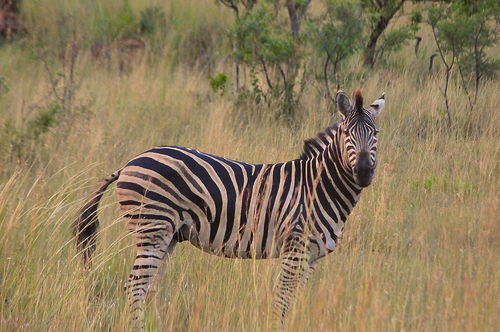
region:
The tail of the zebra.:
[64, 165, 121, 247]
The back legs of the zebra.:
[119, 207, 175, 322]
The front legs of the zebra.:
[274, 245, 311, 330]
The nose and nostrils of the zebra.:
[344, 155, 374, 179]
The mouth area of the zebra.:
[357, 173, 372, 187]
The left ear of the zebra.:
[332, 92, 349, 112]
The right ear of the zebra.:
[372, 89, 389, 115]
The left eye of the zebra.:
[340, 125, 352, 138]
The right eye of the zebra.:
[368, 126, 378, 138]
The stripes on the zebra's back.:
[137, 138, 329, 260]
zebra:
[71, 72, 386, 318]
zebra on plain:
[92, 97, 387, 300]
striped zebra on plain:
[64, 87, 399, 312]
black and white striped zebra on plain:
[68, 84, 389, 313]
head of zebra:
[331, 83, 393, 204]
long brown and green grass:
[8, 10, 196, 139]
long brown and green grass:
[8, 78, 71, 321]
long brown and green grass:
[395, 98, 484, 330]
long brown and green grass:
[79, 16, 499, 75]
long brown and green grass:
[113, 91, 300, 145]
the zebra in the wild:
[56, 48, 435, 310]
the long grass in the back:
[138, 51, 285, 111]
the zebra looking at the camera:
[315, 80, 422, 205]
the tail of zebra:
[67, 196, 115, 267]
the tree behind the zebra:
[202, 12, 459, 98]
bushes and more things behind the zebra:
[58, 43, 273, 155]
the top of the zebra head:
[346, 86, 373, 111]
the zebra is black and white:
[187, 174, 356, 244]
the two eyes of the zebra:
[341, 125, 379, 140]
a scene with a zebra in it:
[44, 26, 483, 328]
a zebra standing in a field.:
[64, 74, 404, 312]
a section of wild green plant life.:
[0, 0, 492, 117]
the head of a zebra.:
[324, 81, 394, 195]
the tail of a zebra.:
[54, 167, 131, 272]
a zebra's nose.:
[341, 150, 387, 194]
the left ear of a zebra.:
[373, 94, 391, 118]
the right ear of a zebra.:
[331, 85, 358, 125]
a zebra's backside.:
[113, 140, 195, 315]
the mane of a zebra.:
[286, 131, 340, 163]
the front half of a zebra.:
[215, 186, 345, 311]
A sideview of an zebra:
[65, 75, 395, 327]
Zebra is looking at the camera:
[305, 77, 410, 217]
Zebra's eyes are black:
[343, 126, 385, 143]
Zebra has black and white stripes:
[58, 108, 405, 324]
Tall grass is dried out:
[5, 76, 499, 329]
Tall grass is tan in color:
[4, 81, 496, 330]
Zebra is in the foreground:
[68, 77, 403, 329]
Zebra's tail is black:
[65, 198, 110, 264]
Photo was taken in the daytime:
[6, 10, 492, 325]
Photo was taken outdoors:
[10, 6, 495, 322]